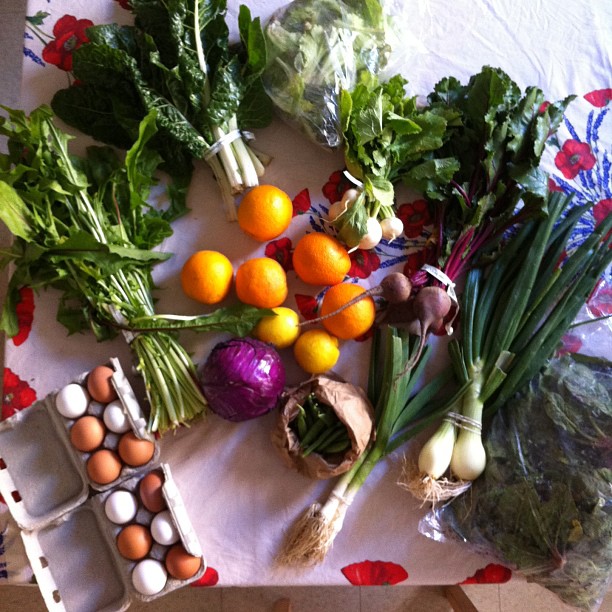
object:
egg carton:
[0, 357, 161, 532]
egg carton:
[22, 460, 206, 611]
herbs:
[417, 351, 610, 612]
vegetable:
[271, 376, 377, 481]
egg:
[117, 524, 150, 560]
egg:
[150, 512, 178, 546]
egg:
[139, 473, 164, 512]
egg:
[55, 383, 90, 418]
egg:
[87, 365, 118, 403]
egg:
[70, 416, 107, 451]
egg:
[103, 402, 131, 433]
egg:
[87, 450, 122, 485]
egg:
[118, 432, 155, 466]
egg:
[105, 490, 138, 524]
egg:
[131, 558, 168, 595]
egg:
[164, 545, 201, 579]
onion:
[199, 336, 285, 423]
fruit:
[238, 185, 293, 242]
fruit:
[181, 250, 234, 304]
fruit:
[235, 256, 288, 308]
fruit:
[292, 232, 351, 285]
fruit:
[253, 307, 300, 348]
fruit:
[320, 282, 376, 339]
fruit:
[294, 328, 341, 373]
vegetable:
[51, 0, 266, 221]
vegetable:
[258, 0, 392, 154]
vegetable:
[396, 190, 610, 517]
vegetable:
[280, 326, 475, 567]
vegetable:
[278, 376, 375, 471]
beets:
[295, 62, 576, 398]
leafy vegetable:
[0, 104, 280, 439]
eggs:
[55, 363, 203, 597]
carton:
[0, 357, 208, 612]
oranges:
[181, 183, 375, 341]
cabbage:
[317, 65, 465, 254]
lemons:
[251, 306, 340, 374]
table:
[0, 0, 612, 587]